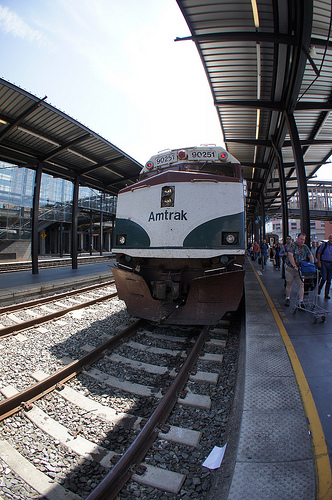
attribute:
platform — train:
[228, 260, 319, 498]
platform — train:
[0, 261, 104, 302]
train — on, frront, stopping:
[104, 139, 253, 332]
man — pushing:
[277, 228, 328, 328]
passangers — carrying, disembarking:
[254, 225, 331, 320]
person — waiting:
[258, 238, 272, 271]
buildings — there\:
[269, 188, 331, 260]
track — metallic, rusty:
[93, 327, 216, 498]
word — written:
[141, 207, 189, 225]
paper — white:
[265, 260, 275, 267]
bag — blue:
[298, 257, 319, 281]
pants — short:
[282, 262, 302, 283]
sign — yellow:
[39, 230, 51, 238]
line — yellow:
[275, 314, 331, 499]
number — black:
[189, 147, 199, 162]